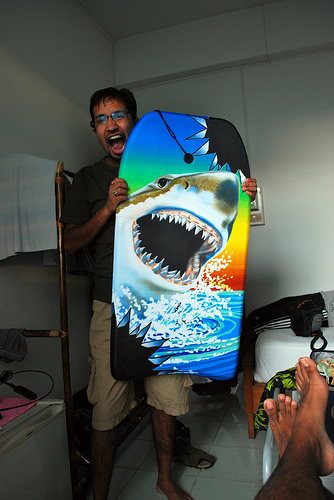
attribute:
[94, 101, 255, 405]
board — shark, surf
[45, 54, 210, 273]
man — wearing, holding, strappy, crossed, hand, excited, standing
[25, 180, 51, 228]
cloth — white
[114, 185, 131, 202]
ring — large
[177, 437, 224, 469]
sandal — brown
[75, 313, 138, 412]
short — khaki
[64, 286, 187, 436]
pant — short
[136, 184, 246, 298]
shark — mouth, decal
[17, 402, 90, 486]
refrigerator — white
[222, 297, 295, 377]
case — gray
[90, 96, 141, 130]
glass — eye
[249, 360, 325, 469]
feet — bare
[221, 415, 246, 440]
floor — grey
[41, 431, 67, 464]
fridge — mini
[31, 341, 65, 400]
wire — black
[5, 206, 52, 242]
towel — white